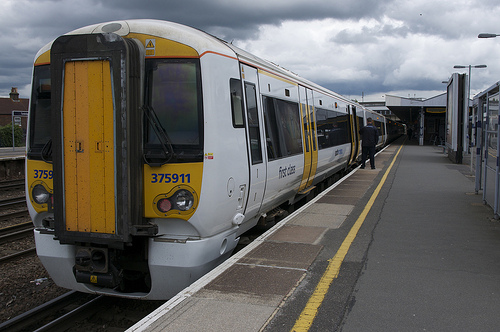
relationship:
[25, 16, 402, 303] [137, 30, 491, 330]
train at station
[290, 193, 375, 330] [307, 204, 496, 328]
yellow line on floor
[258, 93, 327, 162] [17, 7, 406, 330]
window on train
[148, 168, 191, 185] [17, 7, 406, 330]
375911 on train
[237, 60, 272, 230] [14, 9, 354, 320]
white door on train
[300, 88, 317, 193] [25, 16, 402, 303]
double doors on train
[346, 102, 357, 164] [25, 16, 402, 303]
double doors on train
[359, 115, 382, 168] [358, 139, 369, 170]
man left leg